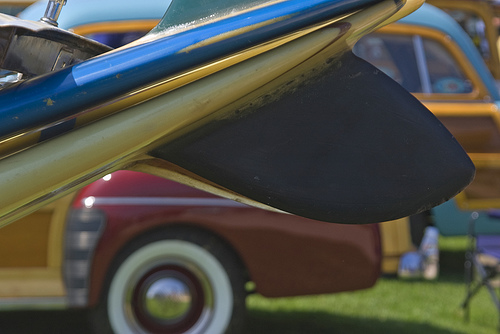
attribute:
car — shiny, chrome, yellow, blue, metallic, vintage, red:
[28, 4, 497, 287]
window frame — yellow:
[377, 22, 485, 109]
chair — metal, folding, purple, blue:
[465, 210, 500, 301]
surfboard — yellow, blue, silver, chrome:
[1, 0, 478, 210]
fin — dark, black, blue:
[155, 56, 475, 219]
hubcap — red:
[141, 278, 189, 324]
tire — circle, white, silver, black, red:
[89, 225, 250, 334]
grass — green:
[246, 279, 500, 334]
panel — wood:
[442, 118, 500, 149]